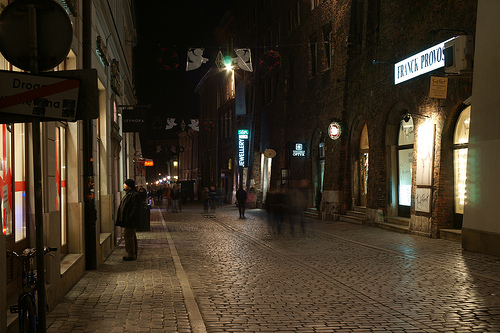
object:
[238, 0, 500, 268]
wall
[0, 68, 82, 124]
sign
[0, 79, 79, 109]
line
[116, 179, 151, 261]
person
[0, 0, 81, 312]
store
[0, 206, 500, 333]
ground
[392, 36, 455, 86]
sign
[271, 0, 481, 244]
building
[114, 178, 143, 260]
man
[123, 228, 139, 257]
pants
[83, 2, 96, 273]
pole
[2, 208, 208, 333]
sidewalk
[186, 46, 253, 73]
decorations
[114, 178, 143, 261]
person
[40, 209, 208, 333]
sidewalk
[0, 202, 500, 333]
street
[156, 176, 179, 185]
bright lights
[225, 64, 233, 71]
light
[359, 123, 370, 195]
windows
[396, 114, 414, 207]
windows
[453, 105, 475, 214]
windows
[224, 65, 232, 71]
light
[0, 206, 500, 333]
road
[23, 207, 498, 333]
floor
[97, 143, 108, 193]
window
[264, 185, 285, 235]
people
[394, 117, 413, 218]
arched doorway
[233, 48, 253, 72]
banner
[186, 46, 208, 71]
banner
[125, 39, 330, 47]
line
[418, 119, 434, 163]
light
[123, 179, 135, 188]
hat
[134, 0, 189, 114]
sky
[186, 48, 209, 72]
angel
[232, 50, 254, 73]
angel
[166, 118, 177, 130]
angel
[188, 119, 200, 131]
angel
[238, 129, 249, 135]
signs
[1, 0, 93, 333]
sign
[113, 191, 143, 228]
jacket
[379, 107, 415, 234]
doorway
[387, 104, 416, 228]
shape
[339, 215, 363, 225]
step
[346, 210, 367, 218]
step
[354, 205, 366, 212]
step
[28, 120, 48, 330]
pole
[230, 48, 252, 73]
decorations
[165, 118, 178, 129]
decorations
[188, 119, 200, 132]
decorations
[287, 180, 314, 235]
people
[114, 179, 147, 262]
people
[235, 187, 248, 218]
people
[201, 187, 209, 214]
people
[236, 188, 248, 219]
person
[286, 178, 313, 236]
person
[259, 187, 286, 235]
person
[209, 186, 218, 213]
person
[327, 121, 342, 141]
light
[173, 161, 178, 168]
light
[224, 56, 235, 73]
light